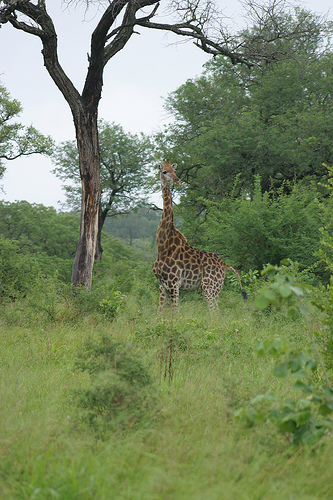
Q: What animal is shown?
A: A giraffe.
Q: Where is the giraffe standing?
A: In the bushes.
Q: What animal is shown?
A: Giraffe.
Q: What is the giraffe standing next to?
A: Tree.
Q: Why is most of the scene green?
A: Vegetation.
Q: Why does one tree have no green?
A: It's dead.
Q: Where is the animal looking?
A: To its left.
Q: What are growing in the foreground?
A: Shrubs.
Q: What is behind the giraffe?
A: Tree.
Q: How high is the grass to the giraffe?
A: Knee high.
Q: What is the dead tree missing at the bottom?
A: Bark.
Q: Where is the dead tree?
A: Next to the giraffe.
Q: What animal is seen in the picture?
A: A giraffe.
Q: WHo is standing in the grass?
A: A giraffe.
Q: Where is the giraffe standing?
A: On the grass.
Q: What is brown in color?
A: The trunk.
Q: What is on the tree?
A: Green leaves.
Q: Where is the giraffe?
A: In a forest.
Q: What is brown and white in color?
A: A giraffe.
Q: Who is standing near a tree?
A: A giraffe.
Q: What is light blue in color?
A: The sky.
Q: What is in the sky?
A: Clouds.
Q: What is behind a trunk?
A: A small tree.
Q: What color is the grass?
A: Green.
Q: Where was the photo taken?
A: In the wild.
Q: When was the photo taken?
A: Daytime.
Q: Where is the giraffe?
A: Next to the tree.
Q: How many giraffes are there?
A: One.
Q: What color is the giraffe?
A: Brown and Tan.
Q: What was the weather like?
A: Cloudy.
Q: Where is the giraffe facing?
A: To the right.